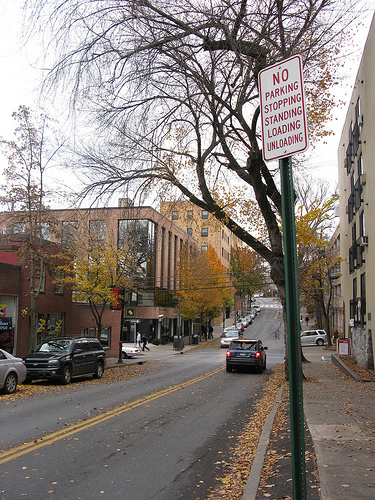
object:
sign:
[257, 53, 308, 161]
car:
[229, 339, 267, 372]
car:
[26, 337, 107, 381]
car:
[0, 346, 29, 393]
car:
[300, 328, 327, 347]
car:
[220, 330, 239, 348]